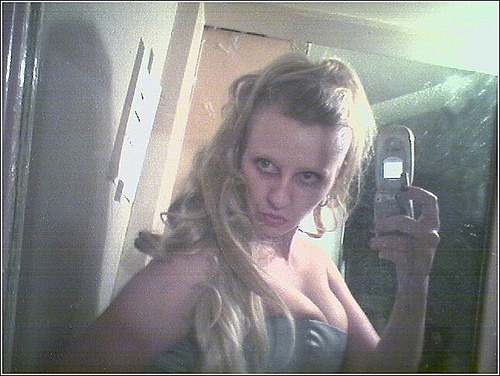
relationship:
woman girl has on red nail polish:
[56, 50, 442, 375] [394, 181, 405, 202]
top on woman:
[214, 307, 369, 374] [171, 78, 411, 366]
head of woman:
[238, 70, 353, 238] [56, 50, 437, 373]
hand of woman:
[370, 183, 441, 290] [56, 50, 437, 373]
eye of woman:
[292, 169, 325, 186] [56, 50, 437, 373]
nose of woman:
[267, 170, 293, 210] [56, 50, 437, 373]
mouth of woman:
[258, 209, 288, 225] [56, 50, 437, 373]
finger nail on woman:
[399, 183, 409, 193] [56, 50, 437, 373]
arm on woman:
[51, 249, 212, 374] [56, 50, 437, 373]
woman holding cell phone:
[56, 50, 437, 373] [373, 124, 413, 234]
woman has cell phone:
[56, 50, 437, 373] [373, 124, 415, 237]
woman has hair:
[56, 50, 437, 373] [133, 53, 378, 375]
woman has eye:
[56, 50, 442, 375] [251, 156, 283, 176]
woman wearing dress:
[56, 50, 442, 375] [147, 316, 350, 374]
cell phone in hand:
[373, 124, 415, 237] [370, 183, 441, 290]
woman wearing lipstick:
[56, 50, 437, 373] [259, 210, 286, 226]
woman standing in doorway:
[56, 50, 442, 375] [3, 2, 499, 372]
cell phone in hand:
[373, 124, 415, 237] [368, 185, 440, 279]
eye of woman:
[247, 144, 277, 174] [162, 76, 382, 358]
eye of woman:
[293, 169, 324, 183] [56, 50, 442, 375]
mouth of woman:
[258, 210, 288, 226] [124, 58, 433, 358]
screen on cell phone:
[382, 155, 400, 181] [373, 124, 415, 237]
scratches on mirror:
[424, 82, 484, 125] [359, 55, 492, 370]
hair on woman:
[143, 59, 260, 374] [56, 50, 437, 373]